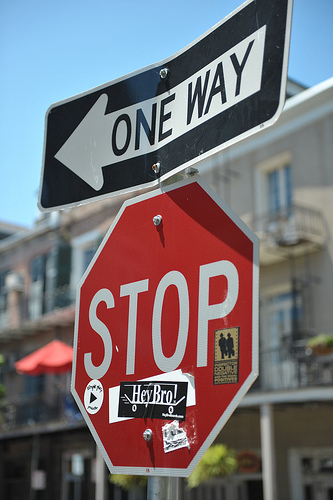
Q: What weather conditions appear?
A: It is clear.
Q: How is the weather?
A: It is clear.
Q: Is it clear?
A: Yes, it is clear.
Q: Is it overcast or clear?
A: It is clear.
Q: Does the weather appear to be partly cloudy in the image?
A: No, it is clear.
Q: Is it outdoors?
A: Yes, it is outdoors.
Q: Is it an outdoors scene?
A: Yes, it is outdoors.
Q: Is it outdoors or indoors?
A: It is outdoors.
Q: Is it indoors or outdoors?
A: It is outdoors.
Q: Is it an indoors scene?
A: No, it is outdoors.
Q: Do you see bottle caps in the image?
A: No, there are no bottle caps.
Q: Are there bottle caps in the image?
A: No, there are no bottle caps.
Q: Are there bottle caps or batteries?
A: No, there are no bottle caps or batteries.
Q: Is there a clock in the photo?
A: No, there are no clocks.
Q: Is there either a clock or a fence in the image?
A: No, there are no clocks or fences.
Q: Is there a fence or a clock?
A: No, there are no clocks or fences.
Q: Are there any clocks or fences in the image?
A: No, there are no clocks or fences.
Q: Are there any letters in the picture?
A: Yes, there are letters.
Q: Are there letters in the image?
A: Yes, there are letters.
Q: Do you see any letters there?
A: Yes, there are letters.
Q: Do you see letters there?
A: Yes, there are letters.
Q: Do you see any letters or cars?
A: Yes, there are letters.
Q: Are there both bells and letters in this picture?
A: No, there are letters but no bells.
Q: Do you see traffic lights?
A: No, there are no traffic lights.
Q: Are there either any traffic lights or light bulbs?
A: No, there are no traffic lights or light bulbs.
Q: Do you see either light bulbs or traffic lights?
A: No, there are no traffic lights or light bulbs.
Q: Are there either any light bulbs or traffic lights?
A: No, there are no traffic lights or light bulbs.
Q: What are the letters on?
A: The letters are on the sign.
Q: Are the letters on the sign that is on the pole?
A: Yes, the letters are on the sign.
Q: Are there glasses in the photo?
A: No, there are no glasses.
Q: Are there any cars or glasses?
A: No, there are no glasses or cars.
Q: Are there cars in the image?
A: No, there are no cars.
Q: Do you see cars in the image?
A: No, there are no cars.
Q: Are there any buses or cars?
A: No, there are no cars or buses.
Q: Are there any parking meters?
A: No, there are no parking meters.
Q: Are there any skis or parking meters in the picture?
A: No, there are no parking meters or skis.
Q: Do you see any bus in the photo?
A: No, there are no buses.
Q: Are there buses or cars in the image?
A: No, there are no buses or cars.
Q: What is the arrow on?
A: The arrow is on the sign.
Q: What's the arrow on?
A: The arrow is on the sign.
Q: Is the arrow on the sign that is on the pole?
A: Yes, the arrow is on the sign.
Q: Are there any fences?
A: No, there are no fences.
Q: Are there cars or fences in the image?
A: No, there are no fences or cars.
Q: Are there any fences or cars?
A: No, there are no fences or cars.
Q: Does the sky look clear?
A: Yes, the sky is clear.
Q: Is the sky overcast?
A: No, the sky is clear.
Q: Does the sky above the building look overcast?
A: No, the sky is clear.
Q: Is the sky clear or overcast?
A: The sky is clear.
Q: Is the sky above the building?
A: Yes, the sky is above the building.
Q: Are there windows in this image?
A: Yes, there is a window.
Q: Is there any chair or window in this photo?
A: Yes, there is a window.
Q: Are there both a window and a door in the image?
A: No, there is a window but no doors.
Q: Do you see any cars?
A: No, there are no cars.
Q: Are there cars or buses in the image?
A: No, there are no cars or buses.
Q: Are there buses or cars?
A: No, there are no cars or buses.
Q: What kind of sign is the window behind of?
A: The window is behind the stop sign.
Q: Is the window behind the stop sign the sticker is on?
A: Yes, the window is behind the stop sign.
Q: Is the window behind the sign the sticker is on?
A: Yes, the window is behind the stop sign.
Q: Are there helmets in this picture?
A: No, there are no helmets.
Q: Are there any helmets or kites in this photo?
A: No, there are no helmets or kites.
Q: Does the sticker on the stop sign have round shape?
A: Yes, the sticker is round.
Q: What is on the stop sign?
A: The sticker is on the stop sign.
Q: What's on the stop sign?
A: The sticker is on the stop sign.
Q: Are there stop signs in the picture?
A: Yes, there is a stop sign.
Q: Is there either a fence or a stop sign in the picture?
A: Yes, there is a stop sign.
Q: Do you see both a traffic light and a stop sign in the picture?
A: No, there is a stop sign but no traffic lights.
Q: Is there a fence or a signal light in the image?
A: No, there are no traffic lights or fences.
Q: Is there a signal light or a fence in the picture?
A: No, there are no traffic lights or fences.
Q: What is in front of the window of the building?
A: The stop sign is in front of the window.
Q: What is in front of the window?
A: The stop sign is in front of the window.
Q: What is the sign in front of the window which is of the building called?
A: The sign is a stop sign.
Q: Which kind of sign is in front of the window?
A: The sign is a stop sign.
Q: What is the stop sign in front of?
A: The stop sign is in front of the window.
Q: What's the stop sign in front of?
A: The stop sign is in front of the window.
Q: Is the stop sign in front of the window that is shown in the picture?
A: Yes, the stop sign is in front of the window.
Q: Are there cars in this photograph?
A: No, there are no cars.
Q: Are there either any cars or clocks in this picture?
A: No, there are no cars or clocks.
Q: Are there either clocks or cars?
A: No, there are no cars or clocks.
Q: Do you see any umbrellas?
A: Yes, there is an umbrella.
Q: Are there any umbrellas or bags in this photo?
A: Yes, there is an umbrella.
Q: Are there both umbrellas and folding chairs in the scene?
A: No, there is an umbrella but no folding chairs.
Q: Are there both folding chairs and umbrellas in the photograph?
A: No, there is an umbrella but no folding chairs.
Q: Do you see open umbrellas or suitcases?
A: Yes, there is an open umbrella.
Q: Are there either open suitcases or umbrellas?
A: Yes, there is an open umbrella.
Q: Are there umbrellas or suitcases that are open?
A: Yes, the umbrella is open.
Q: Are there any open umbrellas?
A: Yes, there is an open umbrella.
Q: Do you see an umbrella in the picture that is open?
A: Yes, there is an umbrella that is open.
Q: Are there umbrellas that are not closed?
A: Yes, there is a open umbrella.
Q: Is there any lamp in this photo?
A: No, there are no lamps.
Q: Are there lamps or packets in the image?
A: No, there are no lamps or packets.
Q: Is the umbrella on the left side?
A: Yes, the umbrella is on the left of the image.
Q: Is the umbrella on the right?
A: No, the umbrella is on the left of the image.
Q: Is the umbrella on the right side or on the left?
A: The umbrella is on the left of the image.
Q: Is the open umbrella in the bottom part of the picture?
A: Yes, the umbrella is in the bottom of the image.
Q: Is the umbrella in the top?
A: No, the umbrella is in the bottom of the image.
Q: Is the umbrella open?
A: Yes, the umbrella is open.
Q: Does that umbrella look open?
A: Yes, the umbrella is open.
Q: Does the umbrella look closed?
A: No, the umbrella is open.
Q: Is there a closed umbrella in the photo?
A: No, there is an umbrella but it is open.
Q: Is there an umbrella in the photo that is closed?
A: No, there is an umbrella but it is open.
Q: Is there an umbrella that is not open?
A: No, there is an umbrella but it is open.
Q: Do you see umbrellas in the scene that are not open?
A: No, there is an umbrella but it is open.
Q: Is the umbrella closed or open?
A: The umbrella is open.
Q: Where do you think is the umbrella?
A: The umbrella is on the balcony.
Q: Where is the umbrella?
A: The umbrella is on the balcony.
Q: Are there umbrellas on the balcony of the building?
A: Yes, there is an umbrella on the balcony.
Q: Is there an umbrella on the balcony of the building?
A: Yes, there is an umbrella on the balcony.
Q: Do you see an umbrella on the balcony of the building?
A: Yes, there is an umbrella on the balcony.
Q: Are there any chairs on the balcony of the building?
A: No, there is an umbrella on the balcony.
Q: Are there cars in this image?
A: No, there are no cars.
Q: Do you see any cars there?
A: No, there are no cars.